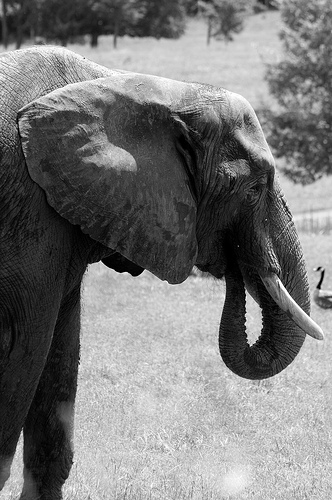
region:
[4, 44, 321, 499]
elephant standing in foreground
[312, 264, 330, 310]
bird in the background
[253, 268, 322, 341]
white tusk of elephant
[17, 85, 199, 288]
ear of gray elephant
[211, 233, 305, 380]
trunk of gray elephant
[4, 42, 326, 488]
elephant and bird walking on grass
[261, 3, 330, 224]
tree behind the bird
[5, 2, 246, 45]
trees behind the gray elephant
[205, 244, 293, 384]
trunk going into elephant's mouth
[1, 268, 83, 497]
front legs of the elephant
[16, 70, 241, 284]
A elephant with big ears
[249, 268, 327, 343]
a tusk of a elephant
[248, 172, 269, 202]
eye of a elephant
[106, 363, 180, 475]
a grassy field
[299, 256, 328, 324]
a duck on the grass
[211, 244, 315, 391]
A large elephant trunk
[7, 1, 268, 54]
trees behind the elephant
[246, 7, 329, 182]
a leafy tree behind the elephant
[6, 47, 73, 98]
winkles on the elephants back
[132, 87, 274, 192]
top of a elephants head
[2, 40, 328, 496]
this is an african elephant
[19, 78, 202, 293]
this elephant has very large ears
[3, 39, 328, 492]
this elephant has very dry skin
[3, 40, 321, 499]
this elephant has very wrinkly skin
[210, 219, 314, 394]
the elephant has his trunk in his mouth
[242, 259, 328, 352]
the elephant has tusks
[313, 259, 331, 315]
the goose has a long neck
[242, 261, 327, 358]
the elephant's tusks are dirty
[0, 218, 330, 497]
the elephant is surrounded by tall grass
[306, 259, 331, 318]
the goose is in the background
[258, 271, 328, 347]
tusk of the elephant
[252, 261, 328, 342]
a tusk of medium length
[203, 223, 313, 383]
trunk in the elephant's mouth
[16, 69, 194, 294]
large ear of an African elephant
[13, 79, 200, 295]
ear of an elephant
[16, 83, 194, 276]
ear of an African elephant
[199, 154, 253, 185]
a spot of sunlight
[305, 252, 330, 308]
water fowl in the background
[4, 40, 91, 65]
a hump on the back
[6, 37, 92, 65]
a hump on the elephant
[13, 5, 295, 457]
an African elephant in a field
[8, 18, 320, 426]
an elephant in a field of grass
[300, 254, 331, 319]
a goose in a field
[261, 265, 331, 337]
the elephant's white tusk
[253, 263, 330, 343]
the tusk looks worn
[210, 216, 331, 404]
the elephant's trunk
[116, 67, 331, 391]
the elephant is sticking its trunk in its mouth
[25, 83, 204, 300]
large ears of an African elephant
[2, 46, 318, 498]
the elephant has rough skin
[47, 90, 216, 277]
there is dry mud on the elephant